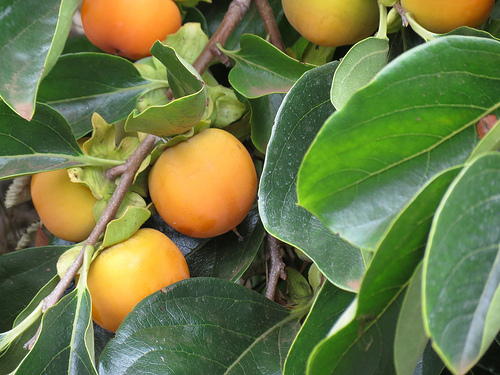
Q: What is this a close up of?
A: Tree.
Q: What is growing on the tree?
A: Fruit.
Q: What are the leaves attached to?
A: Branch.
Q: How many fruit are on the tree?
A: Six.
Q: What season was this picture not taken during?
A: Winter.